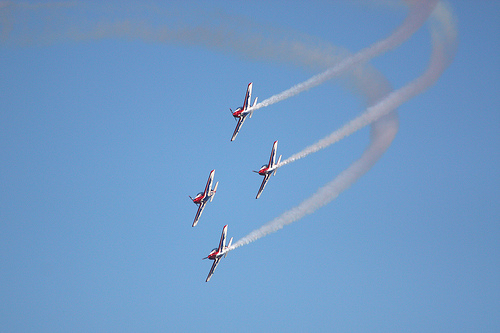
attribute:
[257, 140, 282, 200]
plane — flying , sky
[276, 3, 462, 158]
trail — vapor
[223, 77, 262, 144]
airplane — stunt